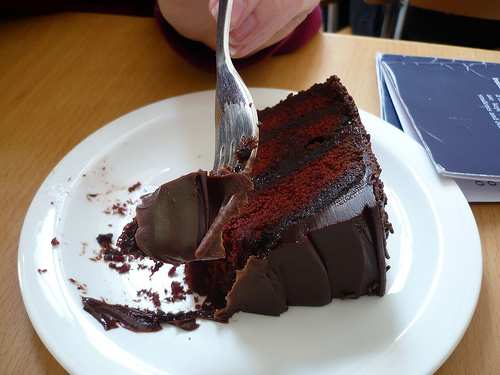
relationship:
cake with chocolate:
[138, 76, 387, 317] [214, 186, 386, 323]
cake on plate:
[138, 76, 387, 317] [16, 87, 485, 373]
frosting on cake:
[80, 74, 393, 333] [138, 76, 387, 317]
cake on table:
[138, 76, 387, 317] [1, 12, 499, 375]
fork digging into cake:
[211, 0, 261, 175] [138, 76, 387, 317]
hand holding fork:
[156, 0, 322, 62] [211, 0, 261, 175]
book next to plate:
[376, 54, 499, 204] [16, 87, 485, 373]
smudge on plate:
[81, 295, 200, 332] [16, 87, 485, 373]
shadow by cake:
[223, 289, 407, 373] [138, 76, 387, 317]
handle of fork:
[214, 0, 233, 62] [211, 0, 261, 175]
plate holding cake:
[16, 87, 485, 373] [138, 76, 387, 317]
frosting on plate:
[81, 181, 196, 329] [16, 87, 485, 373]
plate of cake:
[16, 87, 485, 373] [138, 76, 387, 317]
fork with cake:
[211, 0, 261, 175] [237, 137, 257, 165]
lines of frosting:
[245, 80, 362, 257] [253, 123, 354, 190]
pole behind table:
[392, 0, 412, 41] [1, 12, 499, 375]